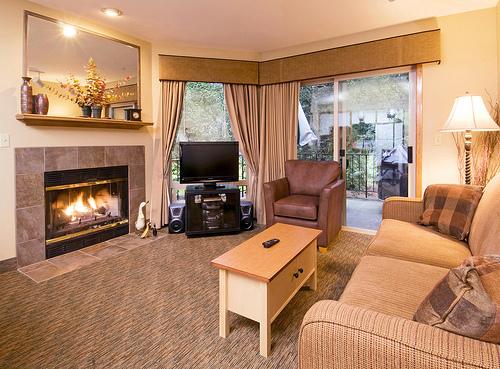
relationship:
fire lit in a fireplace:
[51, 187, 124, 225] [41, 160, 130, 259]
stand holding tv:
[184, 185, 243, 237] [178, 141, 241, 183]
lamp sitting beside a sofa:
[438, 91, 499, 187] [298, 175, 500, 367]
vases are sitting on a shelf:
[20, 75, 50, 115] [17, 113, 155, 131]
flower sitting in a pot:
[43, 56, 136, 106] [91, 104, 103, 119]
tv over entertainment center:
[178, 141, 241, 183] [168, 182, 255, 236]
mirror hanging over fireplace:
[17, 10, 149, 124] [41, 160, 130, 259]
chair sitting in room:
[263, 159, 347, 252] [1, 1, 499, 368]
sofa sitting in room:
[298, 170, 499, 367] [1, 1, 499, 368]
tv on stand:
[178, 141, 241, 183] [184, 185, 243, 237]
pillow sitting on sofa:
[419, 183, 485, 242] [298, 175, 500, 367]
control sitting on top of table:
[261, 236, 280, 247] [211, 220, 322, 357]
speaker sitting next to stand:
[168, 202, 186, 234] [184, 185, 243, 237]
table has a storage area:
[211, 220, 322, 357] [268, 237, 316, 322]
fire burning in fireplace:
[51, 187, 124, 225] [41, 160, 130, 259]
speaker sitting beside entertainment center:
[168, 202, 186, 234] [168, 182, 255, 236]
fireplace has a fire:
[41, 160, 130, 259] [51, 187, 124, 225]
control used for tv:
[262, 238, 280, 248] [178, 141, 241, 183]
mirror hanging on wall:
[17, 10, 149, 124] [1, 1, 153, 261]